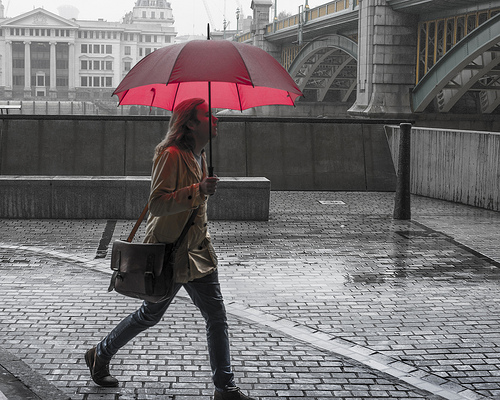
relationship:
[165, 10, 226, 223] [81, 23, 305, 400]
person holding an person holding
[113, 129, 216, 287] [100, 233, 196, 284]
man carrying a brown leather bag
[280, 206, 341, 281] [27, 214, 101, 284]
brick walk way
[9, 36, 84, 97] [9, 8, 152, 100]
pillars on outside of building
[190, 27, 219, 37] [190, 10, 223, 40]
tip of an umbrella top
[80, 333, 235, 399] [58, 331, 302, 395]
man has very brown shoes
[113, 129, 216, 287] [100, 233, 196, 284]
man carrying very brown messenger bag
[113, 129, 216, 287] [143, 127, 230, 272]
man wearing khaki color jacket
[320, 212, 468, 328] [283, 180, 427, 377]
rain on sidewalk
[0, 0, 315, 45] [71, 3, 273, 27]
sky in distance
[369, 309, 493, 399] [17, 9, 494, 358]
jackson mingus took photo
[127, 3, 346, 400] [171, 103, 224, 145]
lady light skinned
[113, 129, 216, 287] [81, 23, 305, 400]
man carrying a red person holding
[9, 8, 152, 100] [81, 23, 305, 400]
wall white person holding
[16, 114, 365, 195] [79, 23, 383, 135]
wall brown in color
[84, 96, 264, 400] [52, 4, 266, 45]
lady walking under sky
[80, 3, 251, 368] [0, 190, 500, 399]
person walking on ground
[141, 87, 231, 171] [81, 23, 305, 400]
head is under person holding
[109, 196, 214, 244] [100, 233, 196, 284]
strap from bag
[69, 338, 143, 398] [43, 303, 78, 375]
heel lifted from ground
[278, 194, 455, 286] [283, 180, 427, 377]
puddles of water on sidewalk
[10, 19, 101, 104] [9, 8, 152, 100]
twi white columns on front of building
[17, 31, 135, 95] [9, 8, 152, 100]
windows on side of building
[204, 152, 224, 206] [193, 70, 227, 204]
hand wrapped around umbrella rod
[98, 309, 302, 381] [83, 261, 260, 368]
wrinkles in pants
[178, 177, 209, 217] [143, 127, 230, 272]
black button on jacket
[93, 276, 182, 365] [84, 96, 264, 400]
right leg belonging to lady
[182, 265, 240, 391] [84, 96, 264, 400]
left leg belonging to lady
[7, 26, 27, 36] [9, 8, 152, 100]
detail adorning building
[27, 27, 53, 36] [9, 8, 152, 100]
detail adorning building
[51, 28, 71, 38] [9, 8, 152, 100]
detail adorning building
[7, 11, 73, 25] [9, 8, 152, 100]
detail adorning building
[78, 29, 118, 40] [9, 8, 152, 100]
detail adorning building